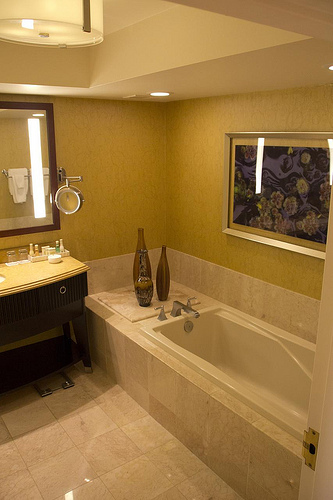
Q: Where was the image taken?
A: It was taken at the bathroom.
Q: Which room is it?
A: It is a bathroom.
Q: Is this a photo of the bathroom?
A: Yes, it is showing the bathroom.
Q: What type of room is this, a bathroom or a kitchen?
A: It is a bathroom.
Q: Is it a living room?
A: No, it is a bathroom.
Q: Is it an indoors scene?
A: Yes, it is indoors.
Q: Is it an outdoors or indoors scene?
A: It is indoors.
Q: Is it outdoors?
A: No, it is indoors.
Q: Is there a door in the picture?
A: Yes, there is a door.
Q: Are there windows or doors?
A: Yes, there is a door.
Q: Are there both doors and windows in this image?
A: No, there is a door but no windows.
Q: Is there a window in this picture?
A: No, there are no windows.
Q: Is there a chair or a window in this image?
A: No, there are no windows or chairs.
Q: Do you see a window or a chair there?
A: No, there are no windows or chairs.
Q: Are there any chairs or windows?
A: No, there are no windows or chairs.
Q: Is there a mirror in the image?
A: Yes, there is a mirror.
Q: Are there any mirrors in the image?
A: Yes, there is a mirror.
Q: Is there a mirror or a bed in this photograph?
A: Yes, there is a mirror.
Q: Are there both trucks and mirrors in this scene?
A: No, there is a mirror but no trucks.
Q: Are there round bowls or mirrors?
A: Yes, there is a round mirror.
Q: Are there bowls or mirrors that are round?
A: Yes, the mirror is round.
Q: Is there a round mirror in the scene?
A: Yes, there is a round mirror.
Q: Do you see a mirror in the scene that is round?
A: Yes, there is a mirror that is round.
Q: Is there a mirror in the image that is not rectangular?
A: Yes, there is a round mirror.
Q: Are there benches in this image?
A: No, there are no benches.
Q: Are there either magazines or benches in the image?
A: No, there are no benches or magazines.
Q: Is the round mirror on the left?
A: Yes, the mirror is on the left of the image.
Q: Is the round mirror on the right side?
A: No, the mirror is on the left of the image.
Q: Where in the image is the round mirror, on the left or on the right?
A: The mirror is on the left of the image.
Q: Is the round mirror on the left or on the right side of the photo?
A: The mirror is on the left of the image.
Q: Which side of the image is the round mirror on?
A: The mirror is on the left of the image.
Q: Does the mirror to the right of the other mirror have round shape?
A: Yes, the mirror is round.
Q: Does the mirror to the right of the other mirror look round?
A: Yes, the mirror is round.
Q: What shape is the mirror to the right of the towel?
A: The mirror is round.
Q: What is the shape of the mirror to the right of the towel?
A: The mirror is round.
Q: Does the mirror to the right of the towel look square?
A: No, the mirror is round.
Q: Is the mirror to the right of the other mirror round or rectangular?
A: The mirror is round.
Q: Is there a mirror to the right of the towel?
A: Yes, there is a mirror to the right of the towel.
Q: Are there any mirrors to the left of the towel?
A: No, the mirror is to the right of the towel.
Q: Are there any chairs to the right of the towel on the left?
A: No, there is a mirror to the right of the towel.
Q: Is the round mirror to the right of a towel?
A: Yes, the mirror is to the right of a towel.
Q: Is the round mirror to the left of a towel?
A: No, the mirror is to the right of a towel.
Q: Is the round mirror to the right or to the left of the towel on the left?
A: The mirror is to the right of the towel.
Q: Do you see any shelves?
A: No, there are no shelves.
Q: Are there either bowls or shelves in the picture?
A: No, there are no shelves or bowls.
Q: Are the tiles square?
A: Yes, the tiles are square.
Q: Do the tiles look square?
A: Yes, the tiles are square.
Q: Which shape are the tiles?
A: The tiles are square.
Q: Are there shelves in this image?
A: No, there are no shelves.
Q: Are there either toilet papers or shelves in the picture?
A: No, there are no shelves or toilet papers.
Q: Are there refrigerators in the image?
A: No, there are no refrigerators.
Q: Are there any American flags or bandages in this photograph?
A: No, there are no American flags or bandages.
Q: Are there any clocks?
A: No, there are no clocks.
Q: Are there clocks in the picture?
A: No, there are no clocks.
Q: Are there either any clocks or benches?
A: No, there are no clocks or benches.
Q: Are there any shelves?
A: No, there are no shelves.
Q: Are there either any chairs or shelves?
A: No, there are no shelves or chairs.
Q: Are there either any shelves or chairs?
A: No, there are no shelves or chairs.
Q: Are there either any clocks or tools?
A: No, there are no clocks or tools.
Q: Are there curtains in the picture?
A: No, there are no curtains.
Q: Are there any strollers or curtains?
A: No, there are no curtains or strollers.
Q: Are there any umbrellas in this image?
A: No, there are no umbrellas.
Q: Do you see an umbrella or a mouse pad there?
A: No, there are no umbrellas or mouse pads.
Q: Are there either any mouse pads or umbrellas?
A: No, there are no umbrellas or mouse pads.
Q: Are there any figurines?
A: No, there are no figurines.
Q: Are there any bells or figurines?
A: No, there are no figurines or bells.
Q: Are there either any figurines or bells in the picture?
A: No, there are no figurines or bells.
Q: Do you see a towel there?
A: Yes, there is a towel.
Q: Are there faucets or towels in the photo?
A: Yes, there is a towel.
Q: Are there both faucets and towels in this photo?
A: Yes, there are both a towel and a faucet.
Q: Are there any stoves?
A: No, there are no stoves.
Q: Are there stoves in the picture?
A: No, there are no stoves.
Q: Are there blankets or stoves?
A: No, there are no stoves or blankets.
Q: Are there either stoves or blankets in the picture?
A: No, there are no stoves or blankets.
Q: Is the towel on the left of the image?
A: Yes, the towel is on the left of the image.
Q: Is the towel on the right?
A: No, the towel is on the left of the image.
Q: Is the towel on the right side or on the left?
A: The towel is on the left of the image.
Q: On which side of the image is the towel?
A: The towel is on the left of the image.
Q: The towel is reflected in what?
A: The towel is reflected in the mirror.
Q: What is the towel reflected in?
A: The towel is reflected in the mirror.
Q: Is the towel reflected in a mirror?
A: Yes, the towel is reflected in a mirror.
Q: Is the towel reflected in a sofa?
A: No, the towel is reflected in a mirror.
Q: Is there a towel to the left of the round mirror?
A: Yes, there is a towel to the left of the mirror.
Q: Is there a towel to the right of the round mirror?
A: No, the towel is to the left of the mirror.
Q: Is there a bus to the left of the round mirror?
A: No, there is a towel to the left of the mirror.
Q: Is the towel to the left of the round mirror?
A: Yes, the towel is to the left of the mirror.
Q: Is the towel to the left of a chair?
A: No, the towel is to the left of the mirror.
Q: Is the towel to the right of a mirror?
A: No, the towel is to the left of a mirror.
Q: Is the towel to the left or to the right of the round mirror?
A: The towel is to the left of the mirror.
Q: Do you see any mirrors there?
A: Yes, there is a mirror.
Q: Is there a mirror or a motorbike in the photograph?
A: Yes, there is a mirror.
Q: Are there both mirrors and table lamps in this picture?
A: No, there is a mirror but no table lamps.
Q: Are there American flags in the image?
A: No, there are no American flags.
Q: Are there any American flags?
A: No, there are no American flags.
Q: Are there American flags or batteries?
A: No, there are no American flags or batteries.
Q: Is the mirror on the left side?
A: Yes, the mirror is on the left of the image.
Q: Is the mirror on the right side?
A: No, the mirror is on the left of the image.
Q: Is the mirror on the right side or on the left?
A: The mirror is on the left of the image.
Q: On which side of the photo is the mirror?
A: The mirror is on the left of the image.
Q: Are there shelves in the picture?
A: No, there are no shelves.